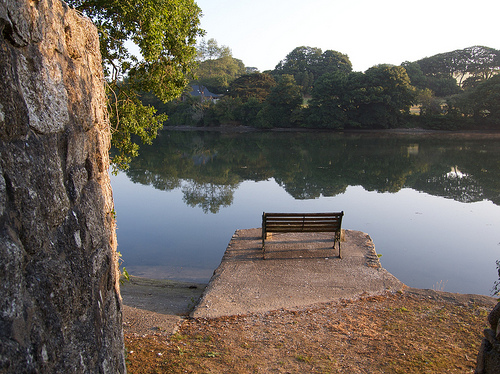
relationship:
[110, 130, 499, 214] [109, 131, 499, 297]
reflection in water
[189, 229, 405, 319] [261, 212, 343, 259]
concrete surface under bench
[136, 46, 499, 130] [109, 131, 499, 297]
trees across water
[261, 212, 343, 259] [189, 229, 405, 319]
bench on concrete surface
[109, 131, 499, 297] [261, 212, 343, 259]
water in front of bench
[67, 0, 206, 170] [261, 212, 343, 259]
tree beside bench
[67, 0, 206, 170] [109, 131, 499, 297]
tree beside water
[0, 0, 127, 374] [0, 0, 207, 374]
tree bark on tree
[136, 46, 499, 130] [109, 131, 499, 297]
trees by water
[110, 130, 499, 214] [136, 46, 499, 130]
reflection of trees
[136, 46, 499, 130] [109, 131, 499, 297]
trees reflect on water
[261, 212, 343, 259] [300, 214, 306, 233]
bench with vertical slat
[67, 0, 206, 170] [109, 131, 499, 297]
tree over water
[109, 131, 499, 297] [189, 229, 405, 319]
water near concrete surface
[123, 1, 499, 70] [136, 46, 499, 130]
sky above trees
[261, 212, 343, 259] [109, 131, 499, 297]
bench overlooking water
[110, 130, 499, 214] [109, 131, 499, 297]
reflection on water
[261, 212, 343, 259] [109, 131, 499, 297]
bench facing water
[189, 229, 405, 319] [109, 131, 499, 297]
concrete surface by water